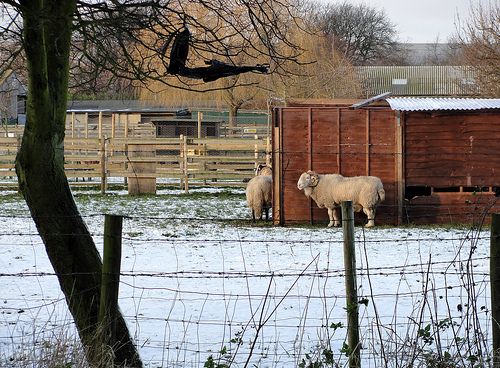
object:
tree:
[1, 0, 318, 365]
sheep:
[295, 170, 387, 229]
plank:
[344, 87, 391, 107]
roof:
[272, 85, 500, 119]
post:
[96, 211, 125, 367]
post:
[486, 212, 499, 366]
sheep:
[239, 162, 277, 219]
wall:
[433, 128, 500, 226]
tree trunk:
[4, 0, 152, 365]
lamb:
[246, 162, 277, 222]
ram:
[295, 170, 386, 228]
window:
[390, 77, 408, 85]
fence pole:
[339, 200, 365, 368]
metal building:
[334, 63, 500, 96]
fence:
[2, 131, 270, 189]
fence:
[3, 206, 499, 366]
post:
[338, 200, 359, 366]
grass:
[0, 178, 490, 253]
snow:
[0, 220, 500, 368]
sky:
[378, 1, 500, 48]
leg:
[364, 205, 377, 223]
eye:
[306, 176, 310, 179]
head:
[297, 171, 321, 191]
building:
[275, 62, 498, 224]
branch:
[68, 1, 328, 91]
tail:
[373, 178, 387, 202]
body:
[244, 173, 270, 210]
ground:
[1, 206, 500, 365]